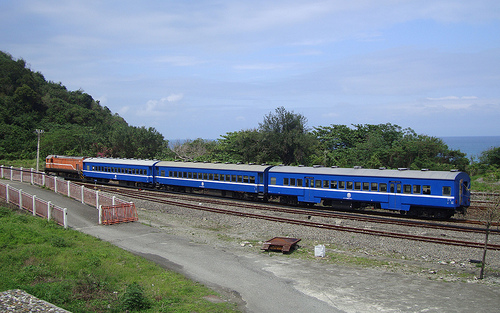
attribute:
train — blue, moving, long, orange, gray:
[43, 154, 473, 219]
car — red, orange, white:
[44, 154, 86, 181]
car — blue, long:
[83, 156, 156, 187]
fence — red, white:
[0, 166, 138, 228]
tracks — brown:
[70, 177, 499, 250]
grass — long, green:
[0, 203, 234, 311]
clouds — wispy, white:
[402, 89, 490, 119]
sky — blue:
[1, 1, 499, 135]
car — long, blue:
[267, 163, 472, 212]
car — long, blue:
[153, 158, 269, 194]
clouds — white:
[37, 7, 312, 46]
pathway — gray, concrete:
[90, 223, 342, 310]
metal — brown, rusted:
[263, 235, 301, 254]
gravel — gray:
[132, 198, 498, 263]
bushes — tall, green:
[49, 100, 93, 127]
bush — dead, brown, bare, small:
[174, 137, 210, 161]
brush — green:
[213, 106, 469, 167]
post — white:
[63, 206, 70, 229]